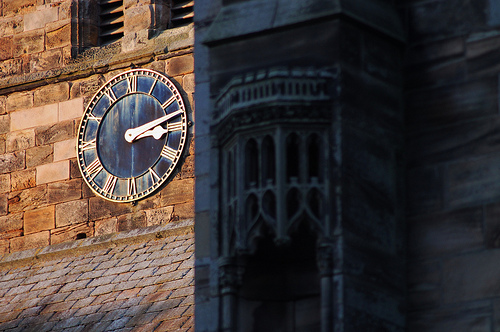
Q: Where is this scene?
A: Outside a building.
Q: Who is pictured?
A: No one.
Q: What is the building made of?
A: Brick.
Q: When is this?
A: Daytime.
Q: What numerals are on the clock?
A: Roman.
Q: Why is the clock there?
A: To tell time.